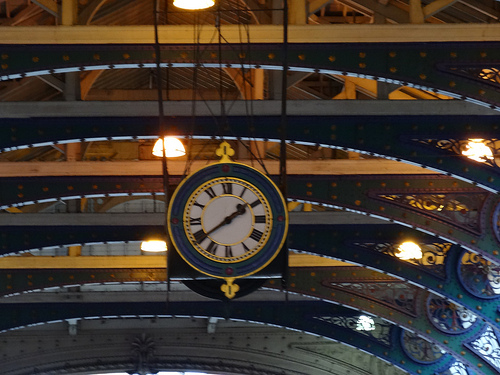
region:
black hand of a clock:
[195, 200, 249, 245]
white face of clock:
[188, 181, 265, 258]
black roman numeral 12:
[220, 180, 233, 194]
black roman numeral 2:
[248, 197, 262, 207]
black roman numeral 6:
[223, 244, 233, 256]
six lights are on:
[140, 0, 494, 330]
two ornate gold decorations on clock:
[213, 140, 240, 300]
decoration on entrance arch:
[125, 330, 161, 373]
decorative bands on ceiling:
[0, 40, 498, 374]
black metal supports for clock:
[152, 0, 290, 307]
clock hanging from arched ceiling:
[163, 141, 290, 299]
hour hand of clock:
[226, 202, 249, 223]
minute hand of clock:
[195, 215, 233, 245]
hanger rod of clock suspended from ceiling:
[151, 1, 176, 211]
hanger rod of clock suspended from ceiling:
[277, 0, 287, 200]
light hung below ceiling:
[137, 237, 167, 252]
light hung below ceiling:
[150, 135, 183, 156]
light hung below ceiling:
[460, 138, 492, 163]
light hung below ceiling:
[393, 238, 420, 259]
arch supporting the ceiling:
[0, 102, 499, 193]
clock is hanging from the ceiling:
[167, 146, 296, 301]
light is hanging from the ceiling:
[152, 135, 187, 157]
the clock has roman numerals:
[182, 180, 277, 263]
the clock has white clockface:
[188, 180, 269, 260]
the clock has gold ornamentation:
[161, 142, 286, 300]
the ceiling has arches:
[0, 78, 497, 369]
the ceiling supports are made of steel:
[285, 267, 434, 329]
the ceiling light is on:
[138, 231, 166, 256]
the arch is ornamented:
[10, 333, 366, 373]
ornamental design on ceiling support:
[379, 190, 491, 230]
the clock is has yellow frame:
[178, 166, 299, 278]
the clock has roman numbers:
[187, 173, 277, 260]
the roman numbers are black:
[241, 191, 268, 234]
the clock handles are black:
[198, 185, 255, 248]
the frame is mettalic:
[283, 101, 424, 179]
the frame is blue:
[337, 118, 432, 160]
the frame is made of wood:
[231, 73, 266, 91]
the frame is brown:
[235, 82, 272, 97]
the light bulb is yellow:
[145, 132, 185, 153]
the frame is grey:
[128, 329, 283, 366]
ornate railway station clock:
[168, 142, 285, 293]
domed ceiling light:
[151, 133, 186, 160]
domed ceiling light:
[140, 240, 166, 258]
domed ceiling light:
[393, 237, 423, 257]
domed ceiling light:
[462, 137, 492, 162]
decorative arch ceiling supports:
[2, 30, 494, 105]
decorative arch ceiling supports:
[0, 162, 496, 262]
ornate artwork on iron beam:
[130, 330, 156, 371]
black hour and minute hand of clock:
[191, 200, 246, 236]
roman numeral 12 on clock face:
[220, 180, 231, 196]